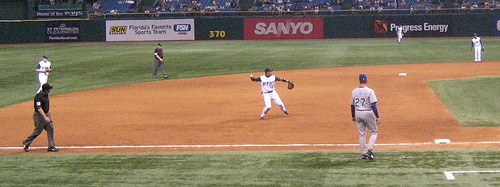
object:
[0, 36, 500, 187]
field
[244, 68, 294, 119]
player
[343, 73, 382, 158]
baseball player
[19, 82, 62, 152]
person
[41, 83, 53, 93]
cap